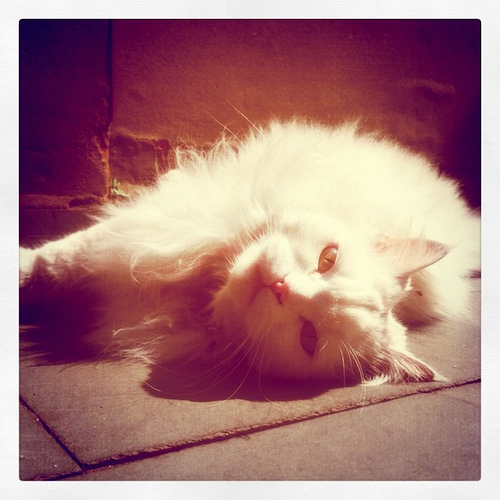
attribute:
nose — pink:
[271, 274, 298, 309]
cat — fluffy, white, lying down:
[18, 97, 497, 405]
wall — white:
[24, 24, 489, 264]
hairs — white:
[376, 214, 432, 266]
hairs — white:
[362, 356, 426, 390]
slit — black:
[322, 254, 335, 266]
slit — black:
[301, 329, 318, 340]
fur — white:
[256, 164, 353, 214]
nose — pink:
[268, 268, 295, 308]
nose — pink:
[253, 266, 294, 300]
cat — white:
[149, 110, 408, 375]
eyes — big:
[294, 244, 354, 370]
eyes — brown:
[294, 232, 355, 375]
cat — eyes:
[294, 232, 335, 364]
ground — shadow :
[66, 356, 336, 465]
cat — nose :
[255, 265, 314, 307]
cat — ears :
[358, 229, 451, 394]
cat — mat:
[51, 354, 202, 437]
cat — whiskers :
[254, 206, 383, 416]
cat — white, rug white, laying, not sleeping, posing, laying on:
[20, 110, 483, 391]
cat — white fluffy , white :
[30, 110, 465, 412]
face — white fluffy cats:
[226, 222, 407, 377]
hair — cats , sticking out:
[327, 222, 392, 317]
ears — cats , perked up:
[350, 225, 462, 395]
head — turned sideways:
[199, 206, 457, 406]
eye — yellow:
[307, 237, 347, 280]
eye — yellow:
[286, 314, 328, 364]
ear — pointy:
[369, 228, 455, 289]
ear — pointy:
[350, 341, 461, 401]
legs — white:
[18, 206, 149, 357]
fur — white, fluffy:
[48, 96, 480, 249]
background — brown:
[20, 18, 481, 264]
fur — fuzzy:
[112, 112, 461, 232]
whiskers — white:
[186, 321, 275, 410]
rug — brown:
[22, 287, 480, 466]